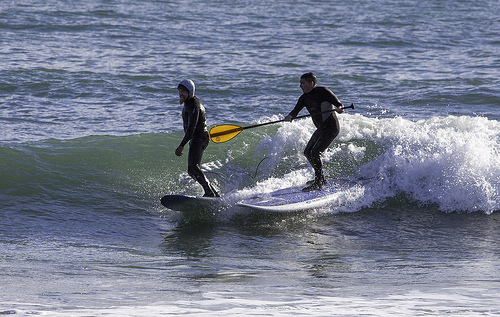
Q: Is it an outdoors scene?
A: Yes, it is outdoors.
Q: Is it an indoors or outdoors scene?
A: It is outdoors.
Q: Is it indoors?
A: No, it is outdoors.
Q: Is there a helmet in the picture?
A: Yes, there is a helmet.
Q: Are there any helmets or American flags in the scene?
A: Yes, there is a helmet.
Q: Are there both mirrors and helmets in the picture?
A: No, there is a helmet but no mirrors.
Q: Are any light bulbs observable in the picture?
A: No, there are no light bulbs.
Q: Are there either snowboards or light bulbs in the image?
A: No, there are no light bulbs or snowboards.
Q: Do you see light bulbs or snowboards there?
A: No, there are no light bulbs or snowboards.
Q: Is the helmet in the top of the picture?
A: Yes, the helmet is in the top of the image.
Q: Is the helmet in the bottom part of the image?
A: No, the helmet is in the top of the image.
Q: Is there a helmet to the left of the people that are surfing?
A: Yes, there is a helmet to the left of the people.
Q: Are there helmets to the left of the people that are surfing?
A: Yes, there is a helmet to the left of the people.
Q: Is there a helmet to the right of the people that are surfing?
A: No, the helmet is to the left of the people.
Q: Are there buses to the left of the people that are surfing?
A: No, there is a helmet to the left of the people.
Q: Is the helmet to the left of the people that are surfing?
A: Yes, the helmet is to the left of the people.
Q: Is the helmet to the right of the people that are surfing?
A: No, the helmet is to the left of the people.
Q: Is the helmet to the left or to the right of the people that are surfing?
A: The helmet is to the left of the people.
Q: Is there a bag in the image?
A: No, there are no bags.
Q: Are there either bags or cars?
A: No, there are no bags or cars.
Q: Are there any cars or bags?
A: No, there are no bags or cars.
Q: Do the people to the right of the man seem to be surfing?
A: Yes, the people are surfing.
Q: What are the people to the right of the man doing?
A: The people are surfing.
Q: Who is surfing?
A: The people are surfing.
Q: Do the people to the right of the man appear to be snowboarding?
A: No, the people are surfing.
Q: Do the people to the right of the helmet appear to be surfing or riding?
A: The people are surfing.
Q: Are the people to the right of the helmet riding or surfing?
A: The people are surfing.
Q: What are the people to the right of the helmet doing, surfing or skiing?
A: The people are surfing.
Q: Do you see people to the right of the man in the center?
A: Yes, there are people to the right of the man.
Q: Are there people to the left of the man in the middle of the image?
A: No, the people are to the right of the man.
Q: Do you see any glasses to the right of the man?
A: No, there are people to the right of the man.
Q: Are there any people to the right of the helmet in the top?
A: Yes, there are people to the right of the helmet.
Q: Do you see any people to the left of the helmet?
A: No, the people are to the right of the helmet.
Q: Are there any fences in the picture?
A: No, there are no fences.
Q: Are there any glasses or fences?
A: No, there are no fences or glasses.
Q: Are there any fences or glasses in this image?
A: No, there are no fences or glasses.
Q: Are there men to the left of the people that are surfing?
A: Yes, there is a man to the left of the people.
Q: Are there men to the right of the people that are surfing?
A: No, the man is to the left of the people.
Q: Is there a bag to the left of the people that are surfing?
A: No, there is a man to the left of the people.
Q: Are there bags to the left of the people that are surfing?
A: No, there is a man to the left of the people.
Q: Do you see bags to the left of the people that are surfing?
A: No, there is a man to the left of the people.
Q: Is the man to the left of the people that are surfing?
A: Yes, the man is to the left of the people.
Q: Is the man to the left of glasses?
A: No, the man is to the left of the people.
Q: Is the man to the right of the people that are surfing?
A: No, the man is to the left of the people.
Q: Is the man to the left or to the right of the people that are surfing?
A: The man is to the left of the people.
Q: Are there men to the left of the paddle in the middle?
A: Yes, there is a man to the left of the oar.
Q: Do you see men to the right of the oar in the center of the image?
A: No, the man is to the left of the paddle.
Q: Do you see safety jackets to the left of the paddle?
A: No, there is a man to the left of the paddle.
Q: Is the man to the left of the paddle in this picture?
A: Yes, the man is to the left of the paddle.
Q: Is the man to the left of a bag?
A: No, the man is to the left of the paddle.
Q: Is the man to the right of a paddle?
A: No, the man is to the left of a paddle.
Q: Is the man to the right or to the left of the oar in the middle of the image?
A: The man is to the left of the paddle.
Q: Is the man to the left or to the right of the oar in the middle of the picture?
A: The man is to the left of the paddle.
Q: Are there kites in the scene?
A: No, there are no kites.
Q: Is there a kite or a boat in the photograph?
A: No, there are no kites or boats.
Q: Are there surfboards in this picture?
A: Yes, there is a surfboard.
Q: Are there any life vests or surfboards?
A: Yes, there is a surfboard.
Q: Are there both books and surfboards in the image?
A: No, there is a surfboard but no books.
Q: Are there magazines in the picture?
A: No, there are no magazines.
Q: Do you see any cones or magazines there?
A: No, there are no magazines or cones.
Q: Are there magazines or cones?
A: No, there are no magazines or cones.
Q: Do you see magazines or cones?
A: No, there are no magazines or cones.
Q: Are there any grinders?
A: No, there are no grinders.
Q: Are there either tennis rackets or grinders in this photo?
A: No, there are no grinders or tennis rackets.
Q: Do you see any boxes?
A: No, there are no boxes.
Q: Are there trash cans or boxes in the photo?
A: No, there are no boxes or trash cans.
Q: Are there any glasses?
A: No, there are no glasses.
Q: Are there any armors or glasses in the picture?
A: No, there are no glasses or armors.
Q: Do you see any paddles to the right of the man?
A: Yes, there is a paddle to the right of the man.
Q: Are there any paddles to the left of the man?
A: No, the paddle is to the right of the man.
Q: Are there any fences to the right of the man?
A: No, there is a paddle to the right of the man.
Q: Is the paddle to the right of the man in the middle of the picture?
A: Yes, the paddle is to the right of the man.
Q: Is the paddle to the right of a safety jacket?
A: No, the paddle is to the right of the man.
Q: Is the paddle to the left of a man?
A: No, the paddle is to the right of a man.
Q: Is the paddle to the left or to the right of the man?
A: The paddle is to the right of the man.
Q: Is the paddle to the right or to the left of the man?
A: The paddle is to the right of the man.